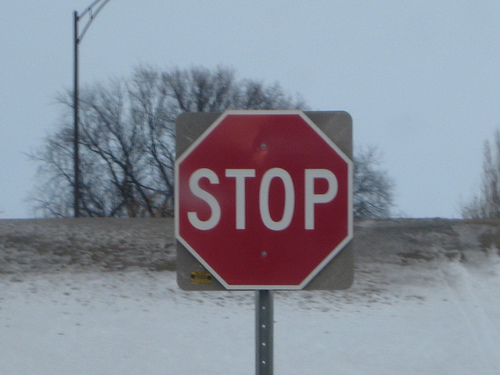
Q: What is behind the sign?
A: Snow.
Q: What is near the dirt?
A: Trees.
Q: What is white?
A: Letters.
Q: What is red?
A: Sign.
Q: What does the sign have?
A: Letters.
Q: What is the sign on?
A: Pole.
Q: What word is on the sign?
A: STOP.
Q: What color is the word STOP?
A: White.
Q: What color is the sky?
A: Blue.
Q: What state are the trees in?
A: Bare.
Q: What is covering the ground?
A: Snow.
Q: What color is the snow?
A: White.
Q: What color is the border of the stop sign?
A: White.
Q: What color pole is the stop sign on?
A: Silver.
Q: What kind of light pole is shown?
A: Metal.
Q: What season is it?
A: Winter.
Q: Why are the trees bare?
A: It's wintertime.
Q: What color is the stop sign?
A: Red.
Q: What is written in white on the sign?
A: Stop.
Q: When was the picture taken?
A: During the daytime.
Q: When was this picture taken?
A: Daytime.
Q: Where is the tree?
A: Behind the stop sign.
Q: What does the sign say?
A: Stop.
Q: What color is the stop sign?
A: Red.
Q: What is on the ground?
A: Snow.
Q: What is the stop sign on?
A: A sign post.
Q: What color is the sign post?
A: Silver.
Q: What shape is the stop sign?
A: Octagon.